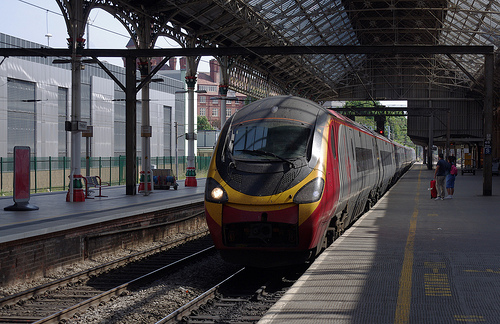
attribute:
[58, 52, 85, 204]
pole — red, green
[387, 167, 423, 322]
stripe — big, yellow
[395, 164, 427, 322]
stripe — big, yellow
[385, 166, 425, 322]
stripe — yellow, big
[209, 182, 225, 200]
light — on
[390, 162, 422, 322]
stripe — yellow, big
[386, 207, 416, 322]
yellow stripe — big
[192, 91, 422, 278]
train — red, yellow, commuter train